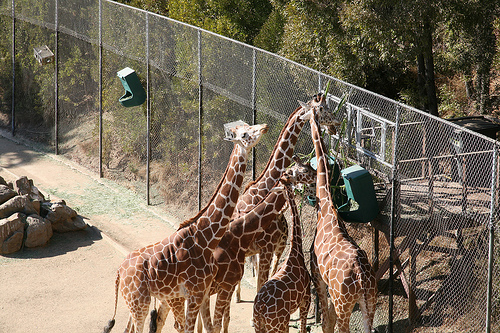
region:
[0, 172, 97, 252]
Large pile of rock on the floor of the enclosure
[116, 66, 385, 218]
Three feed boxes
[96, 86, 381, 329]
Five giraffes at the same feed box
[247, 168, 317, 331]
One small and/or young giraffe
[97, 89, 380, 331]
Four large and/or adult giraffes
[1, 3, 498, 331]
Massive chain link fence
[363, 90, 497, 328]
Wooden platform leading up to feed boxes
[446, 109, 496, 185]
Trash can on platform leading to feed boxes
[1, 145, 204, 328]
Flat floor inside of the enclosure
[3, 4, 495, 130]
Wooded area outside of the enclosure.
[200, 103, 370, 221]
Five zebras gather at the feeding station.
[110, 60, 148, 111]
Green feeding bucket for the animals.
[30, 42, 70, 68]
A small camera to record the zebras.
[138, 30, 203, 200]
A fence to keep people out.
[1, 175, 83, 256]
Pile of rocks in the enclosure.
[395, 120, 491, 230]
Small deck to watch the zebras.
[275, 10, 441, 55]
Bright green trees aside the deck.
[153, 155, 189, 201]
Brown scrub grass outside the fence.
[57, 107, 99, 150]
Small sandy area outside the fence.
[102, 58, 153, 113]
animal feeder hanging on fence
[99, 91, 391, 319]
five giraffe crowded together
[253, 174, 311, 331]
young giraffe in a group of older giraffes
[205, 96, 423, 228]
giraffes enjoying fresh vegetation in their enclosure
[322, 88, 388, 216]
fresh vegetation in feeding boxes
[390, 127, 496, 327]
very tall fence enclosing giraffes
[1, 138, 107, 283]
pile of rocks on floor of giraffe enclosure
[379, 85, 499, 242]
walking bridge viewing area of giraffe pen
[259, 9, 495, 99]
wooded natural area outside of giraffe cage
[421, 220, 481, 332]
small wooden fence below height of giraffe cage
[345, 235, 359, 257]
back of a giraffe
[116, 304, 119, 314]
part of a tail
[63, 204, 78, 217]
edge of a rock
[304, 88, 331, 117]
head of a giraffe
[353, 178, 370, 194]
part of a speaker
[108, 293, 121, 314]
part of a tail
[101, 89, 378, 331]
five giraffes contained in a tall metal wire fence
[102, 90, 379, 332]
African giraffes standing at the feeding bin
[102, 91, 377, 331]
five giraffes looking for food to eat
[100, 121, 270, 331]
a giraffe standing behind other giraffes eating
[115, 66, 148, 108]
an empty green feeding bin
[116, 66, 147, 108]
a feeding bin for the giraffes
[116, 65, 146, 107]
a green bin attached to metal wire fence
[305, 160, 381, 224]
green feeding bins attached to the wire fence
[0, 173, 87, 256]
a pile of rocks inside the giraffe's habitat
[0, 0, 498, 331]
a wire metal fence securing the giraffes